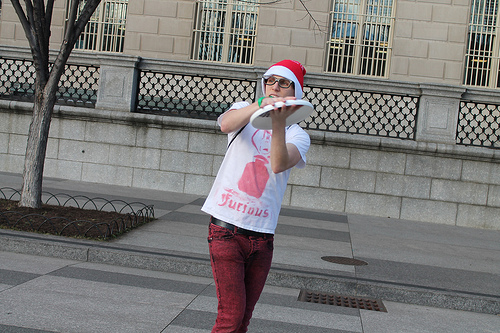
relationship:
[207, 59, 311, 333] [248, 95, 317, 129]
boy catching frisbee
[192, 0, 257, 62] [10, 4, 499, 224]
window on building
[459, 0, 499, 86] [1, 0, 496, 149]
window on building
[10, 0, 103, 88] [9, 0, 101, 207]
branches on tree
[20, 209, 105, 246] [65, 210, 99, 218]
fence around dirt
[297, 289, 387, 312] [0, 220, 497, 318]
rail under curb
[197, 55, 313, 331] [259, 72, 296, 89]
boy wearing eyeglasses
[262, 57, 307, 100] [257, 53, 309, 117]
red cap on head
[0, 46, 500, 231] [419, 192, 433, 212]
wall has part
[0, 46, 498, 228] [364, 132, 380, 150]
wall has edge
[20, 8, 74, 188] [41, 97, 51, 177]
tree has edge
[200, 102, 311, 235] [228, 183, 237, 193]
shirt has part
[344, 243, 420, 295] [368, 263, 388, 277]
road has part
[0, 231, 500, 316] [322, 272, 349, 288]
edge has edge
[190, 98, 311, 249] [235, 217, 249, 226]
shirt has part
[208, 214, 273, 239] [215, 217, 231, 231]
belt has part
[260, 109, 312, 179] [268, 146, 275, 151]
arm has part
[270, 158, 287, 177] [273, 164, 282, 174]
elbow has part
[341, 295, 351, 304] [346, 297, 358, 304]
rail has part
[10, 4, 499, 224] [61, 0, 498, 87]
building has windows